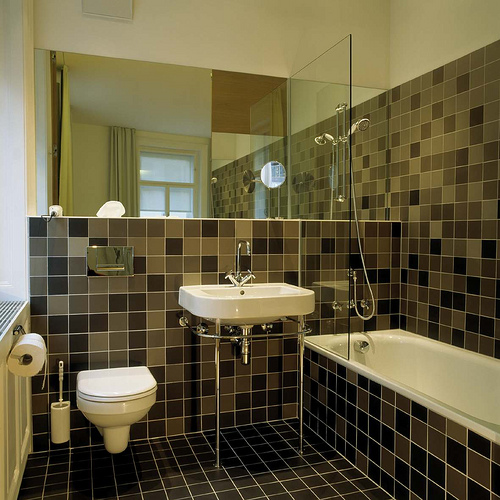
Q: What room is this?
A: The bathroom.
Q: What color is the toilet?
A: White.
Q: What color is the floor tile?
A: Black.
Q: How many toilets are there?
A: One.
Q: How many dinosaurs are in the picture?
A: Zero.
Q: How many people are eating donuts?
A: Zero.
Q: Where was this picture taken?
A: In a bathroom of a home.